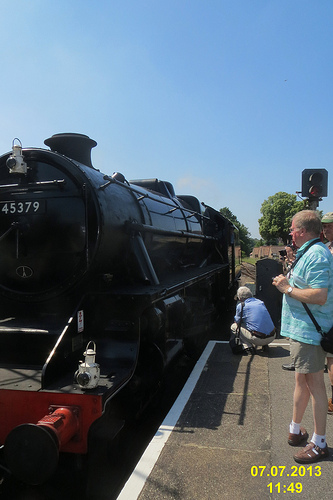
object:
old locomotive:
[0, 131, 247, 497]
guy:
[272, 207, 331, 466]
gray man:
[229, 283, 279, 356]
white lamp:
[77, 343, 101, 389]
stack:
[43, 130, 98, 172]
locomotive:
[0, 127, 226, 430]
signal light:
[301, 166, 326, 203]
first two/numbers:
[0, 200, 16, 215]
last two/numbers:
[24, 200, 40, 215]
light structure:
[75, 343, 102, 395]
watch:
[287, 288, 292, 292]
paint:
[1, 387, 85, 446]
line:
[121, 355, 197, 496]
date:
[247, 467, 323, 476]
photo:
[0, 134, 333, 493]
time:
[254, 481, 306, 494]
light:
[305, 173, 323, 197]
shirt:
[238, 300, 272, 333]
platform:
[161, 352, 282, 497]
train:
[0, 130, 233, 450]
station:
[0, 151, 333, 479]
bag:
[285, 244, 323, 346]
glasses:
[290, 226, 298, 233]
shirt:
[283, 244, 333, 346]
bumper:
[29, 389, 109, 442]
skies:
[0, 1, 325, 167]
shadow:
[168, 354, 260, 431]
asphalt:
[140, 401, 332, 497]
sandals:
[295, 442, 331, 463]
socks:
[307, 435, 324, 446]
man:
[272, 212, 327, 410]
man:
[223, 277, 278, 364]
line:
[174, 418, 312, 469]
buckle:
[315, 445, 325, 454]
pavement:
[188, 334, 273, 496]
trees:
[258, 185, 298, 243]